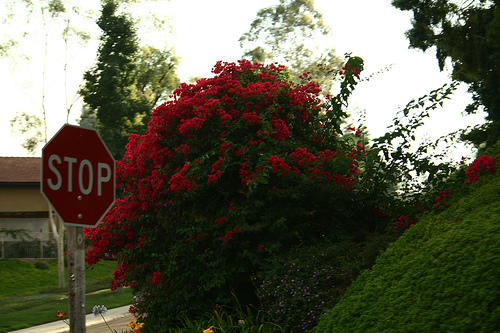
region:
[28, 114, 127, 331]
stop sign on a wooden post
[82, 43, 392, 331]
flowering plant in spring time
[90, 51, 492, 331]
plant on a steep hill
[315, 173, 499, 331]
ground cover on a hill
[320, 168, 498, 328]
ground cover where it is too steep to mow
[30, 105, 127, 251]
sign held by two bolts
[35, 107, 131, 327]
a red and white sign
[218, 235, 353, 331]
a small purple blossom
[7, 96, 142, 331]
an octagonal sign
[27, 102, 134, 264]
an eight sided sign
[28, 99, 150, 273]
the area has a stop sign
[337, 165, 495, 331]
the plants are green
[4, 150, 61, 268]
a building is in the photo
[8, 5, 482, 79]
the sky is clear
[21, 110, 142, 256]
the stop sign is red and white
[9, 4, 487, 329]
the photo was taken outside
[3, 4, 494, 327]
the photo was taken during the day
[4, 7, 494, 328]
nobody is in the photo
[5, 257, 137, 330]
the ground is green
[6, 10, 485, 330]
the weather is calm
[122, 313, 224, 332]
little yellow flowers @ base of big red bush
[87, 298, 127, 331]
long stemmed powder blue flower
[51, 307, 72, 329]
little red+yellow flower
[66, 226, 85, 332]
grimy grungy stop sign pole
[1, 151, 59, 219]
brown roof in the background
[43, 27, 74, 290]
tall thin white trunk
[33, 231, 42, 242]
one pink flower, background bush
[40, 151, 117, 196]
STOP on a sign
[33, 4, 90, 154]
top of tree, long thin branches fading in bright white sun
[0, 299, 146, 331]
little white sidewalk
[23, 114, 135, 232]
a typical stop sign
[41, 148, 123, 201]
large white letters on red background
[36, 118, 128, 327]
a sign on wooden post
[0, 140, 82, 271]
a building with a brown roof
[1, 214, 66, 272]
fence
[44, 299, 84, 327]
flower with red and yellow petals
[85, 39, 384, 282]
a large plant with red flowers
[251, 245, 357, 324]
bush with tiny flowers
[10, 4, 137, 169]
a tall slender tree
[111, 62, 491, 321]
a flowering scene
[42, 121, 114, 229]
the stop sign is red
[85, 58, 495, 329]
the bush has red flowers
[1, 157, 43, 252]
the house is in the background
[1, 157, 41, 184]
the house has a brown roof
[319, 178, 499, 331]
the bush has green leaves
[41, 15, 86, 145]
the tree has a thin trunk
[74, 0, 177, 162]
the tree has green leaves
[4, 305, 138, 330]
the street is paved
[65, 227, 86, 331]
the stop sign is on a wood pole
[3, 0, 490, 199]
the sky is white